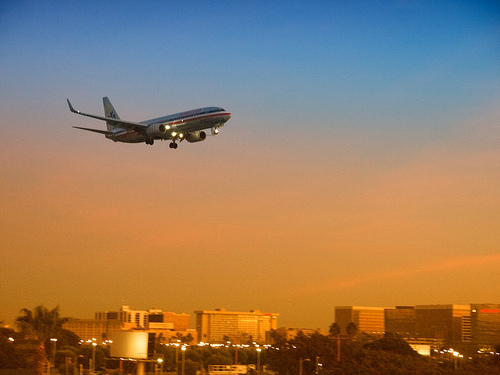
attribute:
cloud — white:
[2, 139, 494, 319]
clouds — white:
[255, 157, 300, 178]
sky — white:
[36, 20, 469, 95]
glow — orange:
[118, 243, 490, 330]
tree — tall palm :
[9, 293, 74, 362]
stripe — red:
[161, 111, 230, 119]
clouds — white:
[324, 142, 424, 211]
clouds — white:
[29, 59, 499, 181]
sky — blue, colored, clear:
[4, 6, 489, 302]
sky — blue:
[298, 112, 376, 153]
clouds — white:
[302, 115, 364, 185]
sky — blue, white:
[0, 0, 497, 344]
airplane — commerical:
[66, 91, 231, 151]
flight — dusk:
[10, 18, 458, 205]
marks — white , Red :
[109, 118, 128, 132]